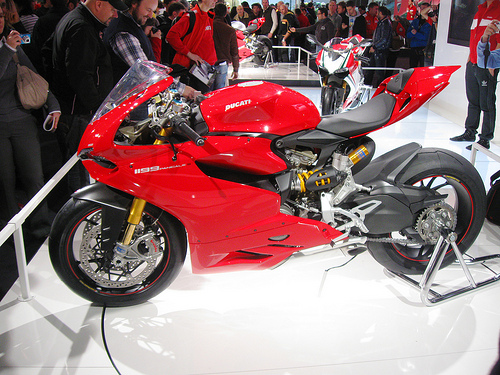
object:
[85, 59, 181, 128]
window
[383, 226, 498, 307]
stand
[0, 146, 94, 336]
light reflection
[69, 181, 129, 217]
fender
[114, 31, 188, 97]
shirt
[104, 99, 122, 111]
sleeve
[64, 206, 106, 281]
outline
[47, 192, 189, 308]
rubber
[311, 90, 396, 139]
surface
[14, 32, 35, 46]
camera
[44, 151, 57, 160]
green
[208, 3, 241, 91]
person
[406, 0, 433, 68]
person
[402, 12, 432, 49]
shirt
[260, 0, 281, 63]
person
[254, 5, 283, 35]
vest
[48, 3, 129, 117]
shirt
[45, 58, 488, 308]
motorbike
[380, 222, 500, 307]
rack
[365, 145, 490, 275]
tire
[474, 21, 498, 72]
man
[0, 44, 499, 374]
stage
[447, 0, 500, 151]
man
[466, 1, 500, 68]
shirt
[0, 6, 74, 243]
woman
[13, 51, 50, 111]
handbag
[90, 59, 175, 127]
windshield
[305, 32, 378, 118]
motorcycle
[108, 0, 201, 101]
men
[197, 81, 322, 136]
gas tank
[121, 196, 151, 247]
shock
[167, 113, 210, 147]
handle bar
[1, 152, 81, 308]
railing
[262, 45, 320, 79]
railing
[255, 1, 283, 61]
person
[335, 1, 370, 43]
person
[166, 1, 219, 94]
man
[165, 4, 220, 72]
sweater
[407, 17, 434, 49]
jacket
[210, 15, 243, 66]
jacket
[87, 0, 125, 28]
head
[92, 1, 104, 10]
ear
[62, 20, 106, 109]
arm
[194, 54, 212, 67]
hand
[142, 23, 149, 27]
chin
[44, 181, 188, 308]
wheel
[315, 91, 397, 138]
seat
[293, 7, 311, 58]
people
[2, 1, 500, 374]
exhibit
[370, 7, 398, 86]
person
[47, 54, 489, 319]
display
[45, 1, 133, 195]
man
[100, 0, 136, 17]
baseball cap